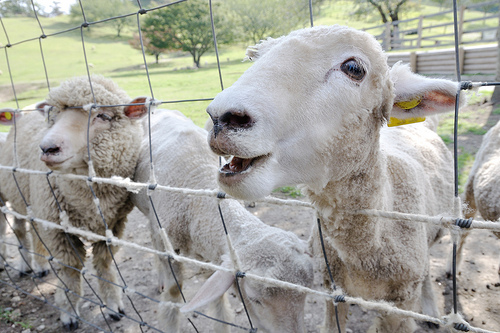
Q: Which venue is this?
A: This is a pen.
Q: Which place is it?
A: It is a pen.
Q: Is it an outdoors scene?
A: Yes, it is outdoors.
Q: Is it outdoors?
A: Yes, it is outdoors.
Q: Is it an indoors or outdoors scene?
A: It is outdoors.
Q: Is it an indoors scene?
A: No, it is outdoors.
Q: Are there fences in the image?
A: Yes, there is a fence.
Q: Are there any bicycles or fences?
A: Yes, there is a fence.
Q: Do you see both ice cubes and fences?
A: No, there is a fence but no ice cubes.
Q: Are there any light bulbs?
A: No, there are no light bulbs.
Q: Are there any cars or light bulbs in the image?
A: No, there are no light bulbs or cars.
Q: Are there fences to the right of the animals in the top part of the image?
A: Yes, there is a fence to the right of the animals.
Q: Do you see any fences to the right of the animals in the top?
A: Yes, there is a fence to the right of the animals.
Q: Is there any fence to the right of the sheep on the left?
A: Yes, there is a fence to the right of the sheep.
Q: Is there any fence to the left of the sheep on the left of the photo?
A: No, the fence is to the right of the sheep.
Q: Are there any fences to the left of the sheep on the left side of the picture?
A: No, the fence is to the right of the sheep.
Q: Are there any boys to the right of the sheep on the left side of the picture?
A: No, there is a fence to the right of the sheep.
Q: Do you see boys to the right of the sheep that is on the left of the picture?
A: No, there is a fence to the right of the sheep.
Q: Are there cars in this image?
A: No, there are no cars.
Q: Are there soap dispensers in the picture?
A: No, there are no soap dispensers.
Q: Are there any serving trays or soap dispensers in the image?
A: No, there are no soap dispensers or serving trays.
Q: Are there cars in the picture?
A: No, there are no cars.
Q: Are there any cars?
A: No, there are no cars.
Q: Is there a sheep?
A: Yes, there is a sheep.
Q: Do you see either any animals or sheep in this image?
A: Yes, there is a sheep.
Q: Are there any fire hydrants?
A: No, there are no fire hydrants.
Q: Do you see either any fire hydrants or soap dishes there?
A: No, there are no fire hydrants or soap dishes.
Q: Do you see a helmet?
A: No, there are no helmets.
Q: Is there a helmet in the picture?
A: No, there are no helmets.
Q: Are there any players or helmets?
A: No, there are no helmets or players.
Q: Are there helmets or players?
A: No, there are no helmets or players.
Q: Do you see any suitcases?
A: No, there are no suitcases.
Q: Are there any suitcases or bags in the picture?
A: No, there are no suitcases or bags.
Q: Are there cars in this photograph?
A: No, there are no cars.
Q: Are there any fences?
A: Yes, there is a fence.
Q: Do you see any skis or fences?
A: Yes, there is a fence.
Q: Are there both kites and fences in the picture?
A: No, there is a fence but no kites.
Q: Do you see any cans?
A: No, there are no cans.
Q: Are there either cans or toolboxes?
A: No, there are no cans or toolboxes.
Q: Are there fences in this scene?
A: Yes, there is a fence.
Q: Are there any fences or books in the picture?
A: Yes, there is a fence.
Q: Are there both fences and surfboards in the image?
A: No, there is a fence but no surfboards.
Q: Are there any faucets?
A: No, there are no faucets.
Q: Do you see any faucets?
A: No, there are no faucets.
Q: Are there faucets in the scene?
A: No, there are no faucets.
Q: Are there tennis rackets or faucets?
A: No, there are no faucets or tennis rackets.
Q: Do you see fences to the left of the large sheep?
A: Yes, there is a fence to the left of the sheep.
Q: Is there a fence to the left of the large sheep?
A: Yes, there is a fence to the left of the sheep.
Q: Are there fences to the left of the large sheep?
A: Yes, there is a fence to the left of the sheep.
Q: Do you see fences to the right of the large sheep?
A: No, the fence is to the left of the sheep.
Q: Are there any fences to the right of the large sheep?
A: No, the fence is to the left of the sheep.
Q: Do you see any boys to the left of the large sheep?
A: No, there is a fence to the left of the sheep.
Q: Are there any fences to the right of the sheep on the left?
A: Yes, there is a fence to the right of the sheep.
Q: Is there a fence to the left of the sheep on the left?
A: No, the fence is to the right of the sheep.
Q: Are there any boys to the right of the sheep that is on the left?
A: No, there is a fence to the right of the sheep.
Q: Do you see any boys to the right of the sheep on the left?
A: No, there is a fence to the right of the sheep.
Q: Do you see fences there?
A: Yes, there is a fence.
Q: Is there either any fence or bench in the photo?
A: Yes, there is a fence.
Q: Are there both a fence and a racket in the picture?
A: No, there is a fence but no rackets.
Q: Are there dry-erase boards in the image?
A: No, there are no dry-erase boards.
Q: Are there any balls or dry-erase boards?
A: No, there are no dry-erase boards or balls.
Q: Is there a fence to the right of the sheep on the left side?
A: Yes, there is a fence to the right of the sheep.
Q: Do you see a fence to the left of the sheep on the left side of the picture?
A: No, the fence is to the right of the sheep.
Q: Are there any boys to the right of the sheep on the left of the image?
A: No, there is a fence to the right of the sheep.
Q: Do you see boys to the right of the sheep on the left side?
A: No, there is a fence to the right of the sheep.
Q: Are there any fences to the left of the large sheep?
A: Yes, there is a fence to the left of the sheep.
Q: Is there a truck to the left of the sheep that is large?
A: No, there is a fence to the left of the sheep.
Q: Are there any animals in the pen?
A: Yes, there are animals in the pen.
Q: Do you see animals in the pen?
A: Yes, there are animals in the pen.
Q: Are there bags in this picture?
A: No, there are no bags.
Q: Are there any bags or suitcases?
A: No, there are no bags or suitcases.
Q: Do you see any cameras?
A: Yes, there is a camera.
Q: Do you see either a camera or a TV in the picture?
A: Yes, there is a camera.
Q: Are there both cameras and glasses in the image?
A: No, there is a camera but no glasses.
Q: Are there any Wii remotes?
A: No, there are no Wii remotes.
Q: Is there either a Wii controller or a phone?
A: No, there are no Wii controllers or phones.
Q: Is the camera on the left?
A: Yes, the camera is on the left of the image.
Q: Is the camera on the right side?
A: No, the camera is on the left of the image.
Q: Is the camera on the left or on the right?
A: The camera is on the left of the image.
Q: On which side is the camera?
A: The camera is on the left of the image.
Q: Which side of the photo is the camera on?
A: The camera is on the left of the image.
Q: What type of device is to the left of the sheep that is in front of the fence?
A: The device is a camera.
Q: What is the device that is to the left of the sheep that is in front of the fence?
A: The device is a camera.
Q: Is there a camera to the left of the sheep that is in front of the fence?
A: Yes, there is a camera to the left of the sheep.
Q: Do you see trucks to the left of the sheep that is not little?
A: No, there is a camera to the left of the sheep.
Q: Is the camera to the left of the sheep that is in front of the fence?
A: Yes, the camera is to the left of the sheep.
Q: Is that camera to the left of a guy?
A: No, the camera is to the left of the sheep.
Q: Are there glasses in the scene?
A: No, there are no glasses.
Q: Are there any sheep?
A: Yes, there is a sheep.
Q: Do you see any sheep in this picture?
A: Yes, there is a sheep.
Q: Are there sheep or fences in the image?
A: Yes, there is a sheep.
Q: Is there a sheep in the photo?
A: Yes, there is a sheep.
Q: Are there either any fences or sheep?
A: Yes, there is a sheep.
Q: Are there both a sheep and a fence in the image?
A: Yes, there are both a sheep and a fence.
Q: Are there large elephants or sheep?
A: Yes, there is a large sheep.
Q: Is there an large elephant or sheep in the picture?
A: Yes, there is a large sheep.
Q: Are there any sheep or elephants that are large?
A: Yes, the sheep is large.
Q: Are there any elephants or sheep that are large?
A: Yes, the sheep is large.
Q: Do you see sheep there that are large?
A: Yes, there is a large sheep.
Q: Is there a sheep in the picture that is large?
A: Yes, there is a sheep that is large.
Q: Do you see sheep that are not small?
A: Yes, there is a large sheep.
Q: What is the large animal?
A: The animal is a sheep.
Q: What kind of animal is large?
A: The animal is a sheep.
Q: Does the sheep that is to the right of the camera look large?
A: Yes, the sheep is large.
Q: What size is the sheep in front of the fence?
A: The sheep is large.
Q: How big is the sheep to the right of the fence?
A: The sheep is large.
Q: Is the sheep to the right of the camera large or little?
A: The sheep is large.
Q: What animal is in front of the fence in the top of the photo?
A: The sheep is in front of the fence.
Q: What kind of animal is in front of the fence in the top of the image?
A: The animal is a sheep.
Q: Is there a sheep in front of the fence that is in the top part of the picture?
A: Yes, there is a sheep in front of the fence.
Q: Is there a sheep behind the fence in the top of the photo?
A: No, the sheep is in front of the fence.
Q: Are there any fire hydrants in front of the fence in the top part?
A: No, there is a sheep in front of the fence.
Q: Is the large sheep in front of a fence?
A: Yes, the sheep is in front of a fence.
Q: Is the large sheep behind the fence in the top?
A: No, the sheep is in front of the fence.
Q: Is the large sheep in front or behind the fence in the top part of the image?
A: The sheep is in front of the fence.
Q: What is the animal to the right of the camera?
A: The animal is a sheep.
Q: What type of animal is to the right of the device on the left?
A: The animal is a sheep.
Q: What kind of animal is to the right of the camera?
A: The animal is a sheep.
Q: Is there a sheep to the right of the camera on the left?
A: Yes, there is a sheep to the right of the camera.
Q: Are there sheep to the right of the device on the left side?
A: Yes, there is a sheep to the right of the camera.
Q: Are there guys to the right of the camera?
A: No, there is a sheep to the right of the camera.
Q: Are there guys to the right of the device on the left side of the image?
A: No, there is a sheep to the right of the camera.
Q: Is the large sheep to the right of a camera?
A: Yes, the sheep is to the right of a camera.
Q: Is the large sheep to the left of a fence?
A: No, the sheep is to the right of a fence.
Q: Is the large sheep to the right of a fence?
A: Yes, the sheep is to the right of a fence.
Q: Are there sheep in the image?
A: Yes, there is a sheep.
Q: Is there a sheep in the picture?
A: Yes, there is a sheep.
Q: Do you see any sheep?
A: Yes, there is a sheep.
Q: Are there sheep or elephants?
A: Yes, there is a sheep.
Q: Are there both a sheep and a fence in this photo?
A: Yes, there are both a sheep and a fence.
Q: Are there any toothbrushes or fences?
A: Yes, there is a fence.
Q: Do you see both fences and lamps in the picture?
A: No, there is a fence but no lamps.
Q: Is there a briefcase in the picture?
A: No, there are no briefcases.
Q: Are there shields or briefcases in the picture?
A: No, there are no briefcases or shields.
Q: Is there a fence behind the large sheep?
A: Yes, there is a fence behind the sheep.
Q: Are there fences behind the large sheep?
A: Yes, there is a fence behind the sheep.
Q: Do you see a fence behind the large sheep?
A: Yes, there is a fence behind the sheep.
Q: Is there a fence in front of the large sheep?
A: No, the fence is behind the sheep.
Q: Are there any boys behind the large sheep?
A: No, there is a fence behind the sheep.